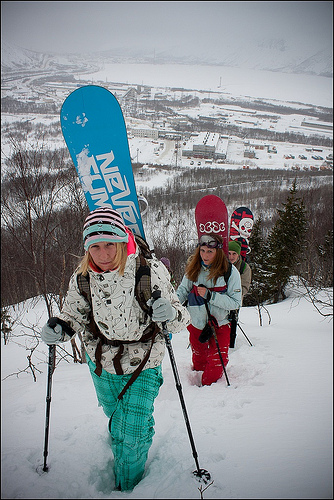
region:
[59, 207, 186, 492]
a woman snow shoeing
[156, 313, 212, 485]
a snow shoe pole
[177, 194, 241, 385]
a woman wearing red pants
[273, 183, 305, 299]
a pine tree in the distance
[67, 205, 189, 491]
a woman wearing a white jacket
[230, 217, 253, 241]
a skull on the snowboard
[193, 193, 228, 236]
the top of a red snowboard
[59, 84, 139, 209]
the top of a blue snowboard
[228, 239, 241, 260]
a person wearing a green cap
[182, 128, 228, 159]
a large building in a distance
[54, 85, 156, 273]
girl with a blue snowboard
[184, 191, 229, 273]
girl with a red snowboard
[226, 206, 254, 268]
person with a skull and bones on their snowboard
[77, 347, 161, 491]
girl wearing green snowpants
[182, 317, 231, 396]
girl wearing red snowpants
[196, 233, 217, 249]
girl wearing goggles on her head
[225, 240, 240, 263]
person wearing a green hat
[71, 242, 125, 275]
girl with blonde hair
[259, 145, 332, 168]
parking lot at the bottom of the hill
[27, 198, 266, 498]
three people walking uphill in deep snow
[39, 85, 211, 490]
a girl carrying a blue snowboard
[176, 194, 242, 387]
a girl carrying a red snowboard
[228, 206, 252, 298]
a boy carrying a snowboard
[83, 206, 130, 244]
a girl's stocking cap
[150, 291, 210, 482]
a girl's left ski pole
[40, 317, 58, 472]
a girl's right ski pole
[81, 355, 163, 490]
a girl's blue snowpants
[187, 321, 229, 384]
a girl's red snowpants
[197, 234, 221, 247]
a girl's snow goggles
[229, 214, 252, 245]
a white skull with red eyes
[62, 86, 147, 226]
The blue snowboard.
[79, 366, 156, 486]
The pants the girl in the front is wearing.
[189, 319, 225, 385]
The pants the girl in the middle is wearing.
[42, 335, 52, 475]
The left ski pole in the girl's hand in the front.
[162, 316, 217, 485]
The ski pole in the girl's hand in the front.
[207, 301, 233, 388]
The ski pole in the girl's hand in the middle.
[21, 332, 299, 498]
The snow the people are walking in.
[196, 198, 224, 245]
The red snowboard in the middle.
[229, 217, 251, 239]
The skull on the snowboard in the back.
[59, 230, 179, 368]
The girl's white and black coat.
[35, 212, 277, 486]
three people hiking up mountain with snowboards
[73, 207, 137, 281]
woman with blonde hair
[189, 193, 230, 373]
woman with a red snowboard on her back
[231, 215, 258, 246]
white skull design on snowboard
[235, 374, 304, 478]
ground covered with snow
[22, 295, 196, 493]
woman holding two black ski poles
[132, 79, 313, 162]
buildings in the distance below mountain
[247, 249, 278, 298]
snow on green trees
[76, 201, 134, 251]
woman wearing knit hat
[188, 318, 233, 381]
woman wearing red ski pants